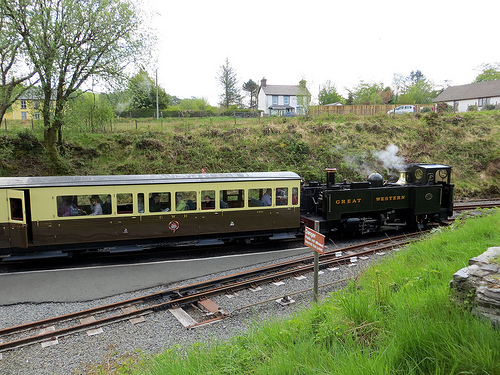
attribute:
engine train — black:
[298, 161, 454, 242]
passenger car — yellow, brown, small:
[0, 169, 301, 269]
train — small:
[1, 162, 457, 268]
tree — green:
[0, 0, 156, 161]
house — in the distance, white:
[256, 75, 311, 120]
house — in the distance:
[432, 79, 500, 113]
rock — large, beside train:
[450, 244, 499, 331]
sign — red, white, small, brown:
[303, 223, 325, 256]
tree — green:
[68, 89, 114, 137]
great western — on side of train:
[333, 194, 407, 206]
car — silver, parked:
[384, 102, 417, 116]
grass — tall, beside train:
[117, 209, 500, 374]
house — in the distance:
[1, 88, 70, 123]